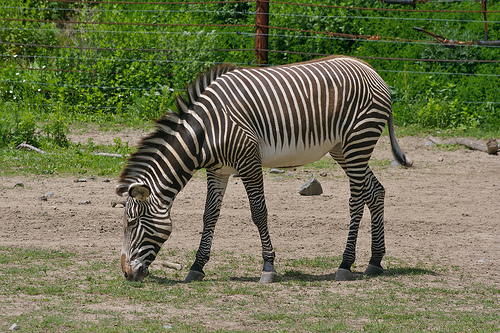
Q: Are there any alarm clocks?
A: No, there are no alarm clocks.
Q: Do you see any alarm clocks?
A: No, there are no alarm clocks.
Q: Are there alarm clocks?
A: No, there are no alarm clocks.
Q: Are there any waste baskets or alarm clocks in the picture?
A: No, there are no alarm clocks or waste baskets.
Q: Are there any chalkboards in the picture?
A: No, there are no chalkboards.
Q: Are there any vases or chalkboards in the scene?
A: No, there are no chalkboards or vases.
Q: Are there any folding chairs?
A: No, there are no folding chairs.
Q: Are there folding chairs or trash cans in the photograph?
A: No, there are no folding chairs or trash cans.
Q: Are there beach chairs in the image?
A: No, there are no beach chairs.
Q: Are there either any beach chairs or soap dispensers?
A: No, there are no beach chairs or soap dispensers.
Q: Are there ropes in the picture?
A: No, there are no ropes.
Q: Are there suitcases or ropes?
A: No, there are no ropes or suitcases.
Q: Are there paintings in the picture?
A: No, there are no paintings.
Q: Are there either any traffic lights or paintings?
A: No, there are no paintings or traffic lights.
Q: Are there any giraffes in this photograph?
A: No, there are no giraffes.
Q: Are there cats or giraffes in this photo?
A: No, there are no giraffes or cats.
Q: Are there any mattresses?
A: No, there are no mattresses.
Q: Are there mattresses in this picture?
A: No, there are no mattresses.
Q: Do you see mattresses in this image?
A: No, there are no mattresses.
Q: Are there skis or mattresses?
A: No, there are no mattresses or skis.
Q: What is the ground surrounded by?
A: The ground is surrounded by the bush.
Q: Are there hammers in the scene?
A: No, there are no hammers.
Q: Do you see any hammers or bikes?
A: No, there are no hammers or bikes.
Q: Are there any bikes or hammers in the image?
A: No, there are no hammers or bikes.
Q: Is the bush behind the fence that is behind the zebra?
A: Yes, the bush is behind the fence.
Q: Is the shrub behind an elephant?
A: No, the shrub is behind the fence.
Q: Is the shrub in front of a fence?
A: No, the shrub is behind a fence.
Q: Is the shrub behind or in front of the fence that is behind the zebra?
A: The shrub is behind the fence.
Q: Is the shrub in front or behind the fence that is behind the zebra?
A: The shrub is behind the fence.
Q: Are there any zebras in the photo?
A: Yes, there is a zebra.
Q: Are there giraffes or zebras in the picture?
A: Yes, there is a zebra.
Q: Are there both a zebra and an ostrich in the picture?
A: No, there is a zebra but no ostriches.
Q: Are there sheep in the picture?
A: No, there are no sheep.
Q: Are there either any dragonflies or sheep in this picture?
A: No, there are no sheep or dragonflies.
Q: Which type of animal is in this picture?
A: The animal is a zebra.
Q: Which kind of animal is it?
A: The animal is a zebra.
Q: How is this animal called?
A: This is a zebra.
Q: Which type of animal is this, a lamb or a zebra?
A: This is a zebra.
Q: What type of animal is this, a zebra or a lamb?
A: This is a zebra.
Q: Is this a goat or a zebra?
A: This is a zebra.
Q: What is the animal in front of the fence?
A: The animal is a zebra.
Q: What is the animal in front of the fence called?
A: The animal is a zebra.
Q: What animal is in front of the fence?
A: The animal is a zebra.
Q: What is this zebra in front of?
A: The zebra is in front of the fence.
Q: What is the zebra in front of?
A: The zebra is in front of the fence.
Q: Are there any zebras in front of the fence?
A: Yes, there is a zebra in front of the fence.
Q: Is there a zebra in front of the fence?
A: Yes, there is a zebra in front of the fence.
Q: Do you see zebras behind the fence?
A: No, the zebra is in front of the fence.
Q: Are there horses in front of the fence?
A: No, there is a zebra in front of the fence.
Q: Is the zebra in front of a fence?
A: Yes, the zebra is in front of a fence.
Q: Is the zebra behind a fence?
A: No, the zebra is in front of a fence.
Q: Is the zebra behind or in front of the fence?
A: The zebra is in front of the fence.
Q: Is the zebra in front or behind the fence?
A: The zebra is in front of the fence.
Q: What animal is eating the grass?
A: The zebra is eating the grass.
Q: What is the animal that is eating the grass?
A: The animal is a zebra.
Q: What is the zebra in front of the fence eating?
A: The zebra is eating grass.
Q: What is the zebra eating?
A: The zebra is eating grass.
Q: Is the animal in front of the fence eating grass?
A: Yes, the zebra is eating grass.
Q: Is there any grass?
A: Yes, there is grass.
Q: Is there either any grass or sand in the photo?
A: Yes, there is grass.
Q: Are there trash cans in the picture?
A: No, there are no trash cans.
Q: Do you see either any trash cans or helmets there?
A: No, there are no trash cans or helmets.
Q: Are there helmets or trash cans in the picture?
A: No, there are no trash cans or helmets.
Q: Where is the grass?
A: The grass is on the ground.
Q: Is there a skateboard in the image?
A: No, there are no skateboards.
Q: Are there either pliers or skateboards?
A: No, there are no skateboards or pliers.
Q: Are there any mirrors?
A: No, there are no mirrors.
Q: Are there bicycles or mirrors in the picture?
A: No, there are no mirrors or bicycles.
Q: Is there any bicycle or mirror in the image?
A: No, there are no mirrors or bicycles.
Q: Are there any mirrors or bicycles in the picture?
A: No, there are no mirrors or bicycles.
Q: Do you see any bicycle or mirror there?
A: No, there are no mirrors or bicycles.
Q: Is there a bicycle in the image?
A: No, there are no bicycles.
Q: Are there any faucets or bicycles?
A: No, there are no bicycles or faucets.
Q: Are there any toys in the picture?
A: No, there are no toys.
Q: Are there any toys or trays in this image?
A: No, there are no toys or trays.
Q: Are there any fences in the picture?
A: Yes, there is a fence.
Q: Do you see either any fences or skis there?
A: Yes, there is a fence.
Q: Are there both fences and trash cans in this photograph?
A: No, there is a fence but no trash cans.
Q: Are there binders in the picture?
A: No, there are no binders.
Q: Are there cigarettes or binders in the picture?
A: No, there are no binders or cigarettes.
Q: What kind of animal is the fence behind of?
A: The fence is behind the zebra.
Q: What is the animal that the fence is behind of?
A: The animal is a zebra.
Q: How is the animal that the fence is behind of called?
A: The animal is a zebra.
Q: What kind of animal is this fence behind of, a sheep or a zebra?
A: The fence is behind a zebra.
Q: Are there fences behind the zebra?
A: Yes, there is a fence behind the zebra.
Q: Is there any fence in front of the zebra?
A: No, the fence is behind the zebra.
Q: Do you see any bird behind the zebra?
A: No, there is a fence behind the zebra.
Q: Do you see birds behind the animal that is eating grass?
A: No, there is a fence behind the zebra.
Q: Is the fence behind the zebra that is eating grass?
A: Yes, the fence is behind the zebra.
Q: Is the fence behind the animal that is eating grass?
A: Yes, the fence is behind the zebra.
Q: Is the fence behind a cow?
A: No, the fence is behind the zebra.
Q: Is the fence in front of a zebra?
A: No, the fence is behind a zebra.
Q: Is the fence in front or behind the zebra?
A: The fence is behind the zebra.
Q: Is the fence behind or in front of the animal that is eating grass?
A: The fence is behind the zebra.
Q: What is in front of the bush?
A: The fence is in front of the shrub.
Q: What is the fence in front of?
A: The fence is in front of the shrub.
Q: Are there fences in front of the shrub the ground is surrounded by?
A: Yes, there is a fence in front of the shrub.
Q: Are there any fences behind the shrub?
A: No, the fence is in front of the shrub.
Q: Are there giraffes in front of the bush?
A: No, there is a fence in front of the bush.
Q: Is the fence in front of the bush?
A: Yes, the fence is in front of the bush.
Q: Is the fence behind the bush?
A: No, the fence is in front of the bush.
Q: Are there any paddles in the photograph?
A: No, there are no paddles.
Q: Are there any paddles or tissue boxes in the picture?
A: No, there are no paddles or tissue boxes.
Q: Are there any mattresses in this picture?
A: No, there are no mattresses.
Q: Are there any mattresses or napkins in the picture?
A: No, there are no mattresses or napkins.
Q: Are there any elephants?
A: No, there are no elephants.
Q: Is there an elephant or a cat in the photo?
A: No, there are no elephants or cats.